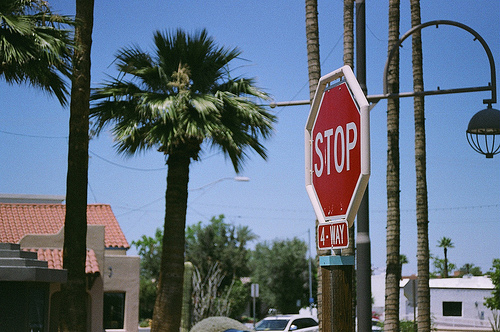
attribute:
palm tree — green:
[88, 18, 279, 328]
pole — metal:
[246, 279, 263, 325]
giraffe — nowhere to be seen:
[93, 20, 278, 184]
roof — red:
[0, 200, 129, 247]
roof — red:
[22, 245, 96, 271]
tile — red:
[4, 189, 125, 289]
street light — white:
[186, 172, 246, 193]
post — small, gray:
[301, 210, 419, 298]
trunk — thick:
[149, 163, 192, 330]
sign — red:
[316, 218, 349, 249]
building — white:
[429, 276, 498, 330]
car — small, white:
[246, 313, 323, 330]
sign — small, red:
[315, 217, 350, 252]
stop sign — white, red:
[303, 67, 368, 221]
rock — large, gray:
[190, 313, 248, 330]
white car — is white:
[255, 314, 321, 330]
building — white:
[12, 165, 177, 328]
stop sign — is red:
[312, 82, 359, 215]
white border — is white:
[302, 65, 370, 249]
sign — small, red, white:
[309, 218, 357, 245]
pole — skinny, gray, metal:
[336, 238, 401, 328]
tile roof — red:
[1, 188, 126, 264]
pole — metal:
[271, 80, 485, 101]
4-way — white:
[318, 223, 345, 243]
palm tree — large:
[83, 29, 270, 330]